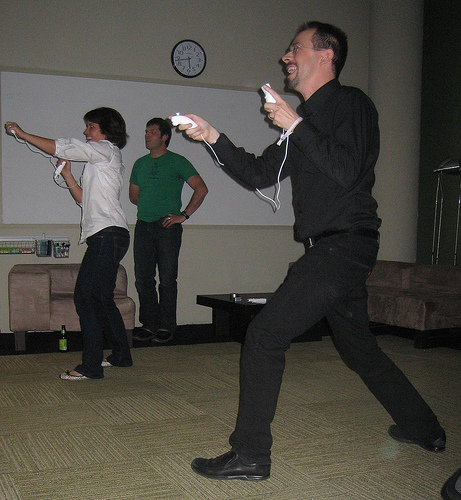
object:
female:
[5, 106, 140, 380]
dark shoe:
[386, 423, 446, 452]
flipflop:
[59, 370, 90, 380]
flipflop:
[101, 359, 114, 367]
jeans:
[73, 225, 132, 379]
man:
[166, 20, 449, 484]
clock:
[170, 39, 206, 79]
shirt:
[204, 77, 383, 244]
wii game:
[163, 79, 278, 134]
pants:
[228, 237, 442, 465]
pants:
[134, 218, 183, 333]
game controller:
[171, 112, 198, 130]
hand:
[262, 84, 300, 129]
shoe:
[135, 327, 154, 342]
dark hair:
[83, 106, 130, 150]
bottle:
[58, 324, 68, 353]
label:
[59, 339, 67, 351]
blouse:
[54, 138, 130, 246]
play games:
[0, 0, 445, 483]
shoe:
[189, 447, 273, 482]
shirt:
[129, 149, 200, 223]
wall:
[2, 4, 421, 349]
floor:
[0, 326, 458, 500]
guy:
[128, 117, 207, 345]